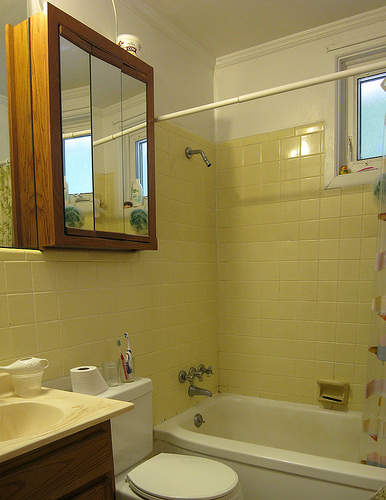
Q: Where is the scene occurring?
A: A bathroom.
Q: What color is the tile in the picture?
A: Yellow.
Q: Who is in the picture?
A: No one.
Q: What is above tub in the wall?
A: A window.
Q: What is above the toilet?
A: A medicine cabinet.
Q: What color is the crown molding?
A: White.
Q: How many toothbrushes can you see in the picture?
A: 2.